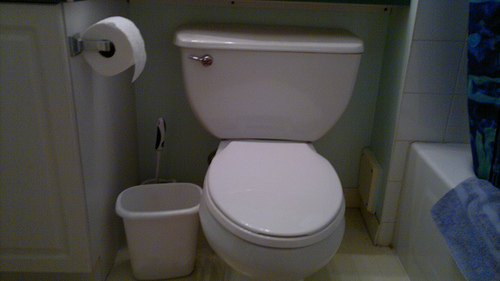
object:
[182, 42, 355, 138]
tank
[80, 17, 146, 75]
roll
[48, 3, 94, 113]
wall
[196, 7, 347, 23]
wall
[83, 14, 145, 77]
paper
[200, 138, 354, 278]
bowl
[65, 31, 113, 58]
holder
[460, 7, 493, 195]
curtain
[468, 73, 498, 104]
pattern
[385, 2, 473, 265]
wall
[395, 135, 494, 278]
bath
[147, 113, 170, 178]
handle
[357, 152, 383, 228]
access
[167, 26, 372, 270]
commode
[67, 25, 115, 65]
bracket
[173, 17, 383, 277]
bowl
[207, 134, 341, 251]
cover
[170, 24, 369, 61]
cover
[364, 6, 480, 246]
tiles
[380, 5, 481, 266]
wall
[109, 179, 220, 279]
bin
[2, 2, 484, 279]
bathroom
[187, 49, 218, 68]
handle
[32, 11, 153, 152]
wall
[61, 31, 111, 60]
dispensor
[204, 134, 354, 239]
seat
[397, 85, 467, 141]
tile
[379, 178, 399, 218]
tile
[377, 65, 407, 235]
wall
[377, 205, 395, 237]
tile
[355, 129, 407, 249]
wall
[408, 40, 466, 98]
tile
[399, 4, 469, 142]
wall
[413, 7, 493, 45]
tile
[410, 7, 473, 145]
wall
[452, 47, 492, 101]
tile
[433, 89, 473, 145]
tile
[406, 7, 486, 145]
wall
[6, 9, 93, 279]
door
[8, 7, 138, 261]
cabinet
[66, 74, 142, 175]
wall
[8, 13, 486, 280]
building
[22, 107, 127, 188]
wall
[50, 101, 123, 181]
building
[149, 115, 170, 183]
brush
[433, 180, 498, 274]
towel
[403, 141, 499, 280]
bathtub